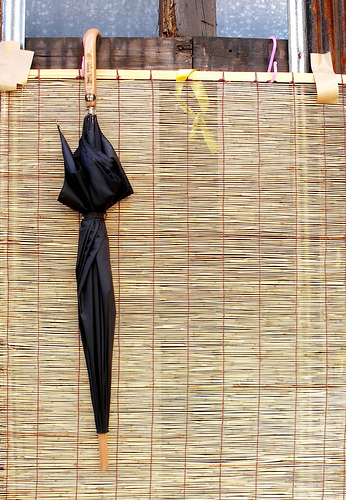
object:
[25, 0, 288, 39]
glass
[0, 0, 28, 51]
siding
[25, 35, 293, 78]
board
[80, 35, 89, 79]
hook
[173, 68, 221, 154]
ribbon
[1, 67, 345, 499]
shade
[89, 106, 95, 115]
metal rod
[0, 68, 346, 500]
basket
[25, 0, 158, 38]
pane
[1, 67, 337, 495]
blind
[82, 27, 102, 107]
handle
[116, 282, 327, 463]
strands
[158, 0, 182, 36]
rotted wood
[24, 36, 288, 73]
rotted wood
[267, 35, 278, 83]
hook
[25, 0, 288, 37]
window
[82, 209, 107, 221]
black strap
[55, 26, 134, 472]
black umbrella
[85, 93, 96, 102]
sticker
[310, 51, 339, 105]
strip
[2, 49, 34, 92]
strip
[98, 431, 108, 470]
tip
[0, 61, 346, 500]
bamboo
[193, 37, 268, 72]
wood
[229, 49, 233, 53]
nail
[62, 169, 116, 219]
leather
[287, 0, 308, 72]
siding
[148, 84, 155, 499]
twine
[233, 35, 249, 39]
edge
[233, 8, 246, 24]
part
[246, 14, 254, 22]
side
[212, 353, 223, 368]
edge